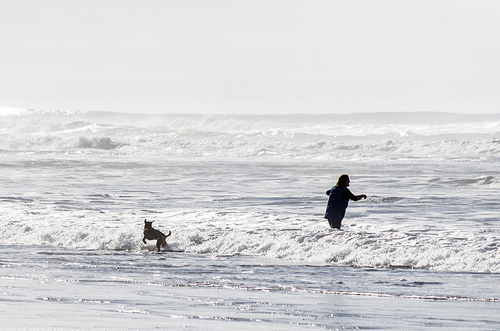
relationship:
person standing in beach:
[314, 163, 362, 251] [37, 103, 489, 324]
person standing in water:
[314, 163, 362, 251] [21, 120, 493, 269]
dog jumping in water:
[138, 211, 169, 252] [21, 120, 493, 269]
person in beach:
[314, 163, 362, 251] [37, 103, 489, 324]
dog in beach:
[138, 211, 169, 252] [37, 103, 489, 324]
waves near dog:
[26, 212, 403, 266] [138, 211, 169, 252]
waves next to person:
[26, 212, 403, 266] [314, 163, 362, 251]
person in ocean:
[314, 163, 362, 251] [30, 110, 498, 310]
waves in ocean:
[26, 212, 403, 266] [30, 110, 498, 310]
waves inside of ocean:
[26, 212, 403, 266] [30, 110, 498, 310]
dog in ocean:
[138, 211, 169, 252] [30, 110, 498, 310]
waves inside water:
[26, 212, 403, 266] [21, 120, 493, 269]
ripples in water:
[46, 170, 283, 212] [21, 120, 493, 269]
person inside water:
[314, 163, 362, 251] [21, 120, 493, 269]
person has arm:
[314, 163, 362, 251] [349, 192, 376, 203]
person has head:
[314, 163, 362, 251] [332, 173, 351, 187]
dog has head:
[138, 211, 169, 252] [142, 217, 154, 228]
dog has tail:
[138, 211, 169, 252] [162, 229, 175, 241]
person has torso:
[314, 163, 362, 251] [338, 183, 345, 200]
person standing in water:
[323, 173, 367, 230] [21, 120, 493, 269]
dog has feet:
[138, 211, 169, 252] [140, 233, 152, 249]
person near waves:
[323, 173, 367, 230] [26, 212, 403, 266]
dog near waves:
[138, 211, 169, 252] [26, 212, 403, 266]